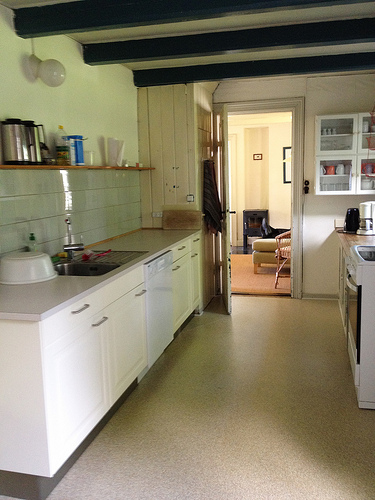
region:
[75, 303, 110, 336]
handles on the cabinet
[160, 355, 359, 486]
the floor is linoleum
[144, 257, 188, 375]
the dishwasher is white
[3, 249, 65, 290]
the cake dish on counter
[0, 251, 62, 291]
the cake dish is white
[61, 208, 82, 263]
the faucet is silver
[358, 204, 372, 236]
coffee maker on the counter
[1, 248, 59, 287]
bowl on a counter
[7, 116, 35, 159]
coffee pot on the shelf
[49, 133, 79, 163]
box on the shelf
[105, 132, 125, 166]
paper towels on the shelf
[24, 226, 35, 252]
soap bottle on the sink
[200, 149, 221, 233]
towel hanging on the door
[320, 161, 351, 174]
cups in a cabinet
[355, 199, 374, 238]
coffee maker on the counter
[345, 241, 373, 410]
stove in the kitchen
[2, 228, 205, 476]
WHITE KITCHEN CABINETS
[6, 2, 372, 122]
HORIZONTAL WOODEN BEAMS ON THE CEILING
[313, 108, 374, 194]
GLASS DOORS ON THE CABINET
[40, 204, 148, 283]
STAINLESS STEEL KITCHEN SINK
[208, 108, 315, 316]
DOOR OPENING TO THE LIVING ROOM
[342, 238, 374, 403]
WHITE STOVE AND OVEN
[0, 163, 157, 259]
TILED BACKSPLASH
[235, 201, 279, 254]
BLACK CHAIR IN THE LIVING ROOM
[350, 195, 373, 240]
WHITE COFFEE MAKER ON THE COUNTERTOP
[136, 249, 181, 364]
A white dishwasher in the cabinet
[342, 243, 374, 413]
A white stove with cooktop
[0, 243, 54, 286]
White bowl on the counter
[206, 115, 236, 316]
Open door to the living room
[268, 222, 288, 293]
Wicker chair in the living room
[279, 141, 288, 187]
Picture frame in the living room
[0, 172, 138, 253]
Glass tile backsplash in kitchen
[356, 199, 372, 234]
White coffee maker on counter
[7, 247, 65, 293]
A plastic bowl on the counter.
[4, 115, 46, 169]
Tea Kettles on the shelf.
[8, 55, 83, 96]
a round light on the wall.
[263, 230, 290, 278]
a chair in the other room.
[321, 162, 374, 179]
Cups in the cabinet.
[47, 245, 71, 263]
A sponge on the kitchen sink.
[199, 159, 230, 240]
A towel hanging on the door.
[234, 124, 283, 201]
The wall is yellow.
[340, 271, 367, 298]
The oven has a white handle.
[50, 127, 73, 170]
A bottle sitting on the shelf.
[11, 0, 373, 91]
darkly painted exposed roof frame timbers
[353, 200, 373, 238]
a white coffee maker sitting on a counter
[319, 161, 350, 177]
upturned coffee mugs sitting on a shelf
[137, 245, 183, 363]
a dishwasher in the kitchen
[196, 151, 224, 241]
a Towel hanging on the wall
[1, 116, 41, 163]
Coffee pot on brown shelf.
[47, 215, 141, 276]
Sink on the kitchen counter.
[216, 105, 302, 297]
Door in between living room and kitchen.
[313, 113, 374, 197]
White cabinet full of cups and silverware.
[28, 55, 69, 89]
White lightbulb in the kitchen.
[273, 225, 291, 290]
Brown wooden chair in the living room.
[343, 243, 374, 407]
White stove in the middle of the kitchen.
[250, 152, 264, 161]
Small picture frame in the living room.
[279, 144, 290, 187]
Large picture frame in the living room.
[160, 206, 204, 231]
Wooden cutting board on the kitchen counter.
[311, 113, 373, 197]
A white framed glass cabinet.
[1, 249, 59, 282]
A white bowl